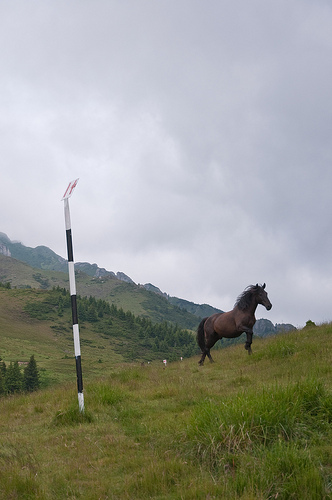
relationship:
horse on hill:
[196, 280, 275, 366] [2, 322, 331, 499]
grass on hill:
[5, 324, 332, 499] [2, 322, 331, 499]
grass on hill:
[107, 367, 140, 383] [2, 322, 331, 499]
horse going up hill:
[196, 280, 275, 366] [2, 322, 331, 499]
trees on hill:
[55, 286, 198, 358] [1, 284, 202, 397]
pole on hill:
[61, 197, 87, 416] [2, 322, 331, 499]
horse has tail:
[196, 280, 275, 366] [196, 317, 209, 353]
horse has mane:
[196, 280, 275, 366] [236, 284, 257, 311]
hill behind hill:
[1, 284, 202, 397] [2, 322, 331, 499]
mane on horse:
[236, 284, 257, 311] [196, 280, 275, 366]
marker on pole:
[61, 177, 84, 198] [61, 197, 87, 416]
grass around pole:
[5, 324, 332, 499] [61, 197, 87, 416]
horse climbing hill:
[196, 280, 275, 366] [2, 322, 331, 499]